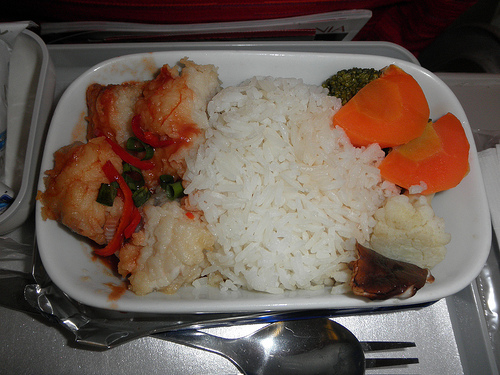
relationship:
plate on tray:
[44, 42, 486, 311] [6, 29, 498, 372]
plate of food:
[44, 42, 486, 311] [82, 68, 461, 276]